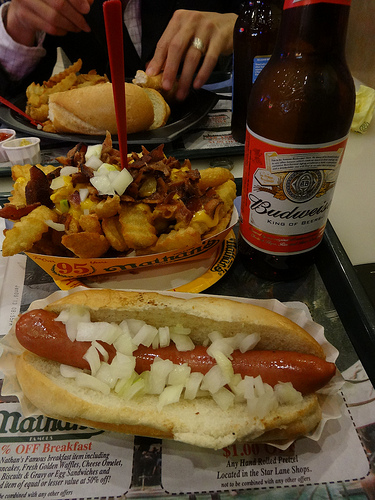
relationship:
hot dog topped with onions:
[3, 289, 343, 437] [67, 311, 280, 404]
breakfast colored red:
[37, 435, 102, 460] [77, 443, 85, 453]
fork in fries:
[91, 5, 161, 174] [27, 167, 239, 255]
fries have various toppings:
[27, 167, 239, 255] [49, 151, 205, 210]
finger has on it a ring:
[173, 24, 221, 100] [190, 39, 207, 53]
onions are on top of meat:
[67, 311, 280, 404] [264, 349, 344, 385]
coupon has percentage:
[1, 396, 146, 494] [0, 442, 18, 468]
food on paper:
[24, 163, 345, 470] [26, 402, 361, 498]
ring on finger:
[190, 39, 207, 53] [173, 24, 221, 100]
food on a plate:
[24, 163, 345, 470] [15, 176, 365, 478]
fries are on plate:
[27, 167, 239, 255] [15, 176, 365, 478]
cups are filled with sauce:
[2, 125, 45, 169] [0, 126, 30, 148]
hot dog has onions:
[3, 289, 343, 437] [67, 311, 280, 404]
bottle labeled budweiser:
[237, 5, 358, 286] [246, 195, 334, 225]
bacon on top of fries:
[2, 170, 56, 224] [27, 167, 239, 255]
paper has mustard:
[11, 140, 40, 174] [9, 133, 37, 150]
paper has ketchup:
[0, 129, 17, 157] [1, 119, 12, 147]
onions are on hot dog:
[67, 311, 280, 404] [3, 289, 343, 437]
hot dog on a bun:
[3, 289, 343, 437] [37, 359, 303, 460]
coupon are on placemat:
[1, 396, 141, 500] [15, 177, 358, 488]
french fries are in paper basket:
[27, 167, 239, 255] [38, 231, 261, 271]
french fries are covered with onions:
[27, 167, 239, 255] [66, 150, 145, 205]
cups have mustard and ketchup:
[2, 125, 45, 169] [0, 126, 30, 148]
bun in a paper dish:
[37, 359, 303, 460] [136, 275, 345, 360]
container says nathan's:
[29, 165, 241, 278] [96, 238, 228, 271]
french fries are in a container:
[27, 167, 239, 255] [29, 165, 241, 278]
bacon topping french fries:
[2, 170, 56, 224] [27, 167, 239, 255]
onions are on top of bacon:
[66, 150, 145, 205] [2, 170, 56, 224]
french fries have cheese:
[27, 167, 239, 255] [129, 167, 157, 193]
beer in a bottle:
[253, 70, 355, 144] [237, 5, 358, 286]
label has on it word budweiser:
[242, 127, 340, 252] [246, 195, 334, 225]